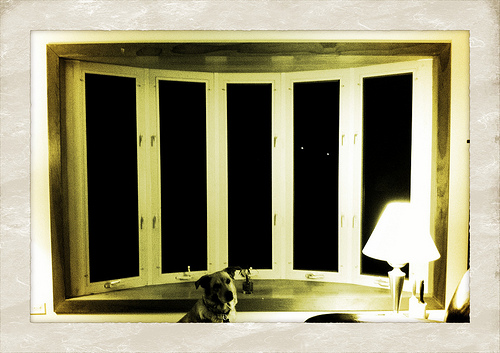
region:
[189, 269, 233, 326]
this is a dog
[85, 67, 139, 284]
A window on a building.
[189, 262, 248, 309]
the head of a dog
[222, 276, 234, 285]
the eye of a dog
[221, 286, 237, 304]
the nose of a dog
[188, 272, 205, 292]
the ear of a dog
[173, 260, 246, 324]
a black and white dog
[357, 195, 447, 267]
a yellow lamp shade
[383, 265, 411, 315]
a metal lamp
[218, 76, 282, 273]
a window in the room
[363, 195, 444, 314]
a lamp in the room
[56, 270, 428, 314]
a gray window ledge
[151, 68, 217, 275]
a window in the room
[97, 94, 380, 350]
the windows are close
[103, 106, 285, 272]
the windows are close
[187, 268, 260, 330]
dog looking directly at camera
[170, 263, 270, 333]
grey and white dog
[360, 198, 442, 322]
lamp with a white lamp shade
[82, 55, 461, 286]
bay window with 5 panes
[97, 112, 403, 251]
night time outside of the window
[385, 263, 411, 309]
silver pedastal of lamp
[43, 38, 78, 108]
brown wood framing window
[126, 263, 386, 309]
shelf in front of windows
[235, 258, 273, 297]
one item on shelf in front of window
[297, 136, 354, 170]
lights in the distance